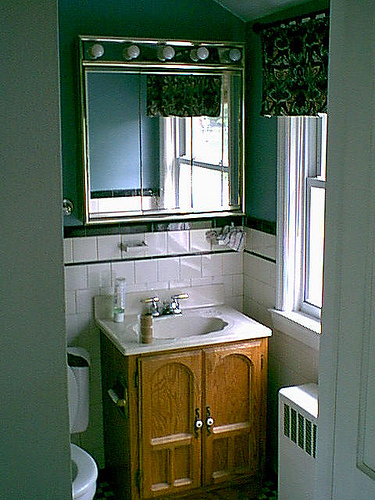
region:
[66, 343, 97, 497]
White toilet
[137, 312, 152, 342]
Empty roll of toilet paper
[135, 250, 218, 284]
White ceramic tile back splash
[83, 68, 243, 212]
Mirror medicine cabinet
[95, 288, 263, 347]
White bathroom sink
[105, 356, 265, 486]
Oak bathroom cabinet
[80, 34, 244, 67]
Five light bulbs above mirror cabinet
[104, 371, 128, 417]
Empty toilet paper holder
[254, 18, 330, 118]
Green valance over window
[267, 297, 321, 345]
White window sill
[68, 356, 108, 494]
A partially hidden toilet.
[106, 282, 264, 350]
A sink in the bathroom.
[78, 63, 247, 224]
A mirror in the bathroom.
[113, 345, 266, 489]
Wood cabinet under the sink.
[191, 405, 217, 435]
Knobs on the cabinet.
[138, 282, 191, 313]
The bathroom sink faucet.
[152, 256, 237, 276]
White tile on the bathroom wall.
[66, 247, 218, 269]
A stripe of blue tile on the wall.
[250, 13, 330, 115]
A curtain in the bathroom.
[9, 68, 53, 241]
The wall is green.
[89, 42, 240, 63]
five lights above the bathroom sink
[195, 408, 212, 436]
knobs on the bathroom sink cupboard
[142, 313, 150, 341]
empty toilet tissue tube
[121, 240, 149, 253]
soap dish mounted to the wall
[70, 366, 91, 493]
white toilet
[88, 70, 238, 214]
mirror above the bathroom sink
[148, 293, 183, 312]
silver and gold sink faucet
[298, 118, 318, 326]
bathroom window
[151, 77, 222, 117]
reflection of the curtain in the miror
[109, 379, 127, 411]
toilet paper holder attached to the cabinet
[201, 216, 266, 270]
hand towel on the wall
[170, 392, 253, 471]
cabinet knobs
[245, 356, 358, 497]
a white heater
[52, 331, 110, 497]
a white toilet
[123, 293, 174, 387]
toilet paper roll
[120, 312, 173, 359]
cardboard toilet paper roll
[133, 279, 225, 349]
silver sink handles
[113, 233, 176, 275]
a soap holder on the wall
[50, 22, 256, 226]
lights on a mirror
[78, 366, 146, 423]
toilet paper holder on a cabinet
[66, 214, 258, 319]
white toilet in the bathroom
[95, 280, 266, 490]
sink in the bathroom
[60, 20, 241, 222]
medicine cabinet in bathroom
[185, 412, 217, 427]
knobs on sink doors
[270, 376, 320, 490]
heater used in the bathroom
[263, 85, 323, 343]
closed bathroom window with curtain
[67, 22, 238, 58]
lights over the bathroom sink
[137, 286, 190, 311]
faucets on the bathroom sink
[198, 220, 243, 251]
used red white and blue washcloth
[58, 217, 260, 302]
black and white tile on bathroom wall